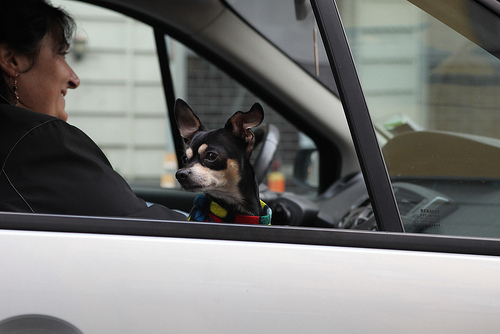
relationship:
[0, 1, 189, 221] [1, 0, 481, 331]
person sitting in car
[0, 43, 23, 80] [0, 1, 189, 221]
ear part of person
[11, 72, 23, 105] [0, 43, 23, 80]
earing worn in ear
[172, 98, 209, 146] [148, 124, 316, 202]
ear located on head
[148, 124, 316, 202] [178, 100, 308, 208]
head part of dog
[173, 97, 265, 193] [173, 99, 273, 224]
head part of dog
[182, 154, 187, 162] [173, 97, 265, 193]
eye located in head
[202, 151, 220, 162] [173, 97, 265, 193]
eye located in head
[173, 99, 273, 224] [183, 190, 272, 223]
dog wearing clothes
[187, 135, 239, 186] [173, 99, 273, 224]
face part of dog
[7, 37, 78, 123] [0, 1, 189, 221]
face part of person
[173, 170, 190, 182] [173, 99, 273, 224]
nose part of dog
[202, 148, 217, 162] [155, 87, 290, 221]
eye part of dog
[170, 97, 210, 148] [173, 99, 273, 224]
ear part of dog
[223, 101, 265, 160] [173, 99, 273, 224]
ear part of dog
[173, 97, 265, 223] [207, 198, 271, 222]
dog wearing clothes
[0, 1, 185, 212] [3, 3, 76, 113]
person has hair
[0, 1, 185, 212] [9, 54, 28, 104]
person wearing earring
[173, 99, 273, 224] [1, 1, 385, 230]
dog looking out window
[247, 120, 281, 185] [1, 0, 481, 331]
steering wheel part of car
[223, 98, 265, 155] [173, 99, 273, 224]
ear part of dog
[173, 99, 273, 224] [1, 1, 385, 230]
dog sitting at window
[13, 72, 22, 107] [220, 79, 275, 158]
earing worn on ear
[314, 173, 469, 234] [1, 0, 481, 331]
dash in car